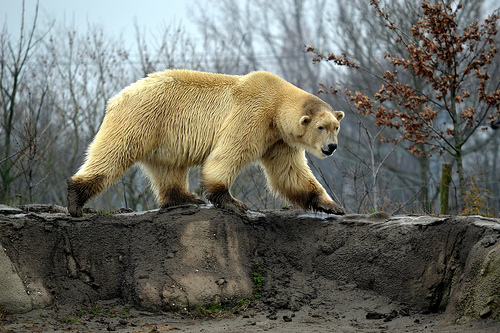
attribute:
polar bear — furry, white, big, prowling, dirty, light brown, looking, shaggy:
[65, 68, 346, 217]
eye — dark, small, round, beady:
[317, 125, 325, 131]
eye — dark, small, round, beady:
[335, 127, 338, 131]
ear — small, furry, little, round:
[298, 115, 312, 126]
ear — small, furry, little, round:
[336, 111, 345, 122]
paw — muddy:
[309, 198, 347, 215]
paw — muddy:
[205, 189, 250, 212]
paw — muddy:
[158, 193, 206, 208]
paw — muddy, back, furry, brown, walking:
[65, 175, 84, 219]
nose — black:
[329, 143, 338, 150]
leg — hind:
[138, 162, 205, 210]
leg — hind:
[80, 128, 139, 190]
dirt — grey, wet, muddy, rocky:
[1, 204, 499, 333]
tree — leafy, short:
[308, 0, 499, 216]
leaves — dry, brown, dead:
[304, 45, 362, 69]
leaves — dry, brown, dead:
[370, 2, 413, 49]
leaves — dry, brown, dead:
[458, 12, 499, 40]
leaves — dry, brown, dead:
[473, 69, 489, 100]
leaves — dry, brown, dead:
[401, 143, 448, 160]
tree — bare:
[2, 1, 57, 205]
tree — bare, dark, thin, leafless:
[43, 12, 113, 174]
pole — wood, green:
[438, 162, 453, 216]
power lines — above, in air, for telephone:
[2, 52, 387, 75]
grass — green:
[82, 200, 115, 215]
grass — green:
[63, 297, 132, 324]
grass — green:
[195, 300, 245, 309]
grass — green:
[252, 261, 269, 300]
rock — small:
[281, 314, 292, 322]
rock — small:
[248, 320, 256, 327]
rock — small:
[216, 278, 226, 286]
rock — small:
[412, 317, 422, 324]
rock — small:
[119, 319, 127, 325]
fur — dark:
[280, 189, 317, 206]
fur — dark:
[206, 181, 231, 200]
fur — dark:
[161, 185, 185, 197]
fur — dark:
[73, 174, 106, 201]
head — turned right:
[299, 98, 343, 158]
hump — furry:
[236, 71, 291, 87]